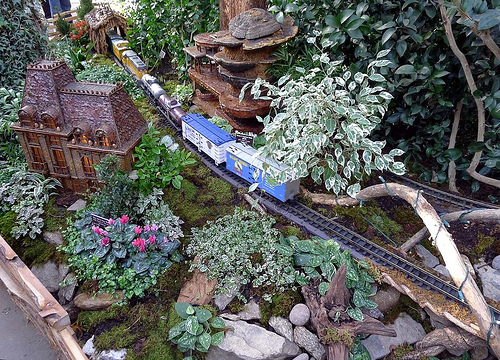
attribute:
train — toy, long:
[110, 32, 306, 205]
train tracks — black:
[103, 34, 479, 309]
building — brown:
[8, 55, 150, 192]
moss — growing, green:
[161, 173, 238, 223]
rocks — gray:
[174, 270, 330, 360]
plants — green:
[63, 124, 196, 297]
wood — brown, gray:
[176, 0, 300, 135]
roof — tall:
[19, 57, 150, 140]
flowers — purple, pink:
[88, 215, 175, 265]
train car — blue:
[224, 141, 305, 202]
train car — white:
[180, 112, 238, 170]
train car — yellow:
[120, 50, 150, 82]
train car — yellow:
[111, 35, 127, 62]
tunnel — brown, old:
[83, 5, 136, 54]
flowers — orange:
[68, 19, 87, 42]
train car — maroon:
[157, 92, 185, 125]